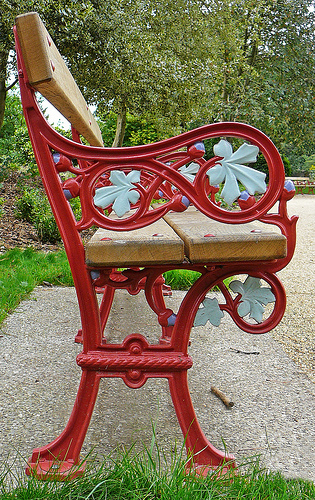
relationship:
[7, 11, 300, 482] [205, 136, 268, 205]
bench with design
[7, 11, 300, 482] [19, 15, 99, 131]
bench with back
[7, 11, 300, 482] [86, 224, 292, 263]
bench with seat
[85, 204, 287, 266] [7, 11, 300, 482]
bolts of bench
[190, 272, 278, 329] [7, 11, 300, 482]
leaf design on bench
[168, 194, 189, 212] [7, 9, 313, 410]
flower on bench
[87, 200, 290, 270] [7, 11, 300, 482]
seat of bench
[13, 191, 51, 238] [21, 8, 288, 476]
bush behind bench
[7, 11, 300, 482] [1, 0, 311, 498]
bench in park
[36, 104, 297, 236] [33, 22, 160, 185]
arms on bench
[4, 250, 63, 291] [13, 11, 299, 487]
grass around bench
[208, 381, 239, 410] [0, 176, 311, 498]
twigs on ground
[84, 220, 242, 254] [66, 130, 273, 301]
bolts on seat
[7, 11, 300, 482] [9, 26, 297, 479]
bench with metal work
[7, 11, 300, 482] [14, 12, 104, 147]
bench made with back